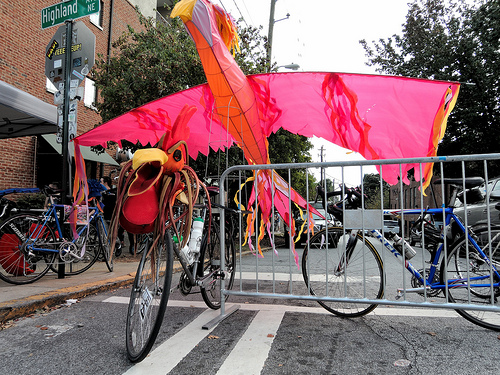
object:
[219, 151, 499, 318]
rack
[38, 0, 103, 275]
street sign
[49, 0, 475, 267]
kite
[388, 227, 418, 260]
water bottle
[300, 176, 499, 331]
bicycle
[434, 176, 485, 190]
seat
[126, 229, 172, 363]
tire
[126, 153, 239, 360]
bicycle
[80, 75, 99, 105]
window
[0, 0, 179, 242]
building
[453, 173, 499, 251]
cars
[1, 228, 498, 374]
street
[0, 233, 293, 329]
sidewalk